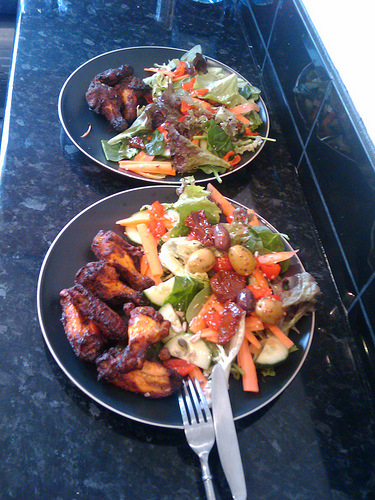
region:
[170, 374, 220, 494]
a silver fork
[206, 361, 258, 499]
a silver knife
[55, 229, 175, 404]
pieces of chicken on a dish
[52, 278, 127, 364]
the wing is fried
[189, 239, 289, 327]
two small potatoes color brown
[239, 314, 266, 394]
the slices of carrots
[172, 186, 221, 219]
a piece of lettuce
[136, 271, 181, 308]
a slice of cucumber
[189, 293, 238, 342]
a slice of tomato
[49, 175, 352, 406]
black plate on granite counter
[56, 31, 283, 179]
black plate on granite counter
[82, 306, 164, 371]
chicken on black plate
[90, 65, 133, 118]
chicken on black plate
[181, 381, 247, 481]
metal forf on counter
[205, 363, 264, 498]
metal knife on counter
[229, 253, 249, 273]
green olives on plate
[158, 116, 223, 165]
green lettuce on plate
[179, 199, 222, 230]
green lettuce on plate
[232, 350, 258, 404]
orange carrots on plate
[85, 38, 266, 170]
the food is colorful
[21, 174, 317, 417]
food on the plate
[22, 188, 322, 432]
the plate is black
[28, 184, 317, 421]
the edge of the plate is white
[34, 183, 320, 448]
the plate is white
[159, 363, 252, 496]
knife and fork on the plate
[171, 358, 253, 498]
the utensils are silver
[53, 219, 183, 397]
the chicken is brown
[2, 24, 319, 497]
two plates on counter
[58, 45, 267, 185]
plate full of food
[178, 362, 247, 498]
two utensils on plate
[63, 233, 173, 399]
cooked chicken wings on plate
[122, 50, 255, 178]
pile of salad on plate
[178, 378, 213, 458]
fork prong with light reflection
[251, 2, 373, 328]
tile wall over counter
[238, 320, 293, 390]
carrot slices in salad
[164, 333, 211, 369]
half of a cucumber slice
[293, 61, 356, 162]
reflection of plate on wall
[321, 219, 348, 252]
part fo a line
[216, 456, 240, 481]
edge fo a knife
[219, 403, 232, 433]
part of a knife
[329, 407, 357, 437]
part of a shade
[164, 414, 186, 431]
edge of a plate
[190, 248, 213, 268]
A piece of food.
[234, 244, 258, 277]
A piece of food.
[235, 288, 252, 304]
A piece of food.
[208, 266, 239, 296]
A piece of food.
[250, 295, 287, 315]
A piece of food.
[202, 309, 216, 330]
A piece of food.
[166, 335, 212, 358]
A piece of food.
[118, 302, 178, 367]
A piece of food.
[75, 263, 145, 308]
A piece of food.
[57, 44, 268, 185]
Plate with three pieces of chicken.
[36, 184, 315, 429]
Plate with more chicken.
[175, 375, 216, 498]
Silver fork with four tines.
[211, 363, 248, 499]
A silver knife on a plate.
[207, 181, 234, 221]
Carrot coming off a plate near another plate.